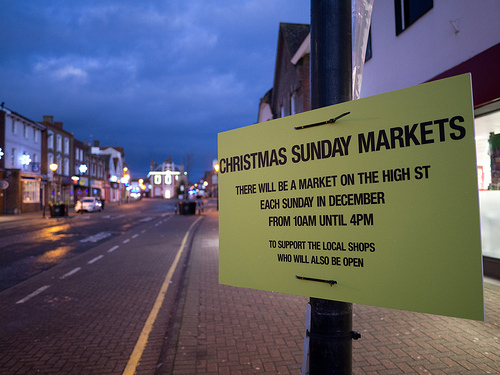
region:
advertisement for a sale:
[208, 74, 493, 317]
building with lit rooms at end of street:
[143, 153, 190, 195]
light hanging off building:
[21, 153, 36, 172]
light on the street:
[45, 161, 64, 176]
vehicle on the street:
[76, 191, 104, 213]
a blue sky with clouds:
[22, 6, 239, 121]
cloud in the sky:
[46, 50, 106, 87]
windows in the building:
[156, 173, 178, 185]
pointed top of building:
[261, 10, 304, 69]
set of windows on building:
[45, 133, 75, 173]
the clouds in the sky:
[0, 0, 310, 185]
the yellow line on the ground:
[119, 204, 214, 374]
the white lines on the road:
[15, 208, 175, 304]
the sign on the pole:
[216, 73, 486, 321]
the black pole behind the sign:
[310, 1, 354, 374]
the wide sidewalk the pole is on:
[162, 209, 497, 374]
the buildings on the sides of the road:
[0, 0, 499, 282]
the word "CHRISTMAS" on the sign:
[218, 147, 287, 174]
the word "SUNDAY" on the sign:
[290, 136, 351, 163]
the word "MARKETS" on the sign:
[356, 116, 466, 153]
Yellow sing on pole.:
[211, 124, 471, 306]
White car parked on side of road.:
[78, 194, 102, 211]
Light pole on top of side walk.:
[46, 160, 61, 219]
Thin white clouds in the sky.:
[36, 68, 148, 111]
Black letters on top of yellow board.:
[214, 150, 299, 172]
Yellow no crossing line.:
[145, 241, 177, 351]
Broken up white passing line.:
[17, 279, 54, 306]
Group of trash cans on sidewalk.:
[46, 201, 69, 215]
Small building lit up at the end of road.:
[147, 158, 189, 200]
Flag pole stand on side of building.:
[441, 5, 465, 37]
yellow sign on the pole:
[181, 92, 498, 337]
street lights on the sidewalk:
[25, 148, 92, 179]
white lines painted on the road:
[43, 223, 142, 292]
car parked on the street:
[73, 193, 104, 213]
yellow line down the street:
[114, 292, 163, 359]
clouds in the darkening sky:
[54, 13, 165, 115]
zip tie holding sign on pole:
[296, 108, 349, 140]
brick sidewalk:
[199, 305, 266, 371]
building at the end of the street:
[148, 160, 187, 213]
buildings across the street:
[11, 112, 118, 216]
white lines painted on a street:
[6, 215, 166, 327]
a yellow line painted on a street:
[133, 207, 203, 374]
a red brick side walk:
[158, 309, 294, 369]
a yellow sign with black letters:
[202, 104, 483, 306]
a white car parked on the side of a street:
[53, 184, 108, 224]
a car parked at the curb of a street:
[71, 184, 113, 224]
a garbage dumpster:
[174, 192, 199, 221]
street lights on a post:
[25, 158, 130, 195]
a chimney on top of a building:
[43, 115, 70, 126]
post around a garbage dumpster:
[166, 194, 209, 218]